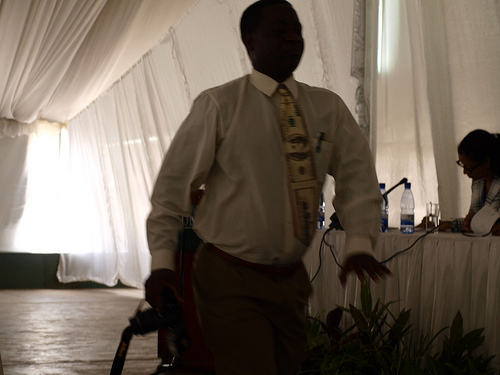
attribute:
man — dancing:
[145, 1, 391, 374]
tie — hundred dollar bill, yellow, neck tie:
[269, 84, 319, 246]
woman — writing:
[415, 129, 499, 235]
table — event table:
[303, 226, 499, 359]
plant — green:
[342, 294, 397, 375]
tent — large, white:
[0, 2, 500, 289]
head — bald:
[240, 2, 305, 75]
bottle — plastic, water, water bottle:
[401, 183, 414, 233]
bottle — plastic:
[378, 182, 388, 232]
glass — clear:
[425, 203, 438, 230]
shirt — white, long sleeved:
[147, 70, 383, 274]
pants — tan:
[167, 228, 313, 374]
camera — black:
[132, 295, 178, 336]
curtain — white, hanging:
[1, 0, 106, 247]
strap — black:
[133, 296, 149, 324]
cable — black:
[311, 224, 333, 283]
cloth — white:
[303, 230, 499, 359]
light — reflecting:
[14, 289, 85, 374]